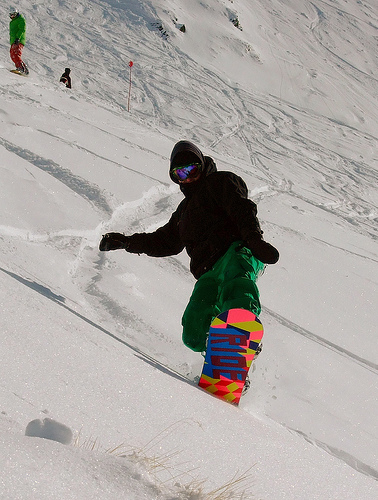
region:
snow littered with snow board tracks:
[161, 69, 281, 123]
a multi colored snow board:
[190, 313, 266, 395]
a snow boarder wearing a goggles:
[116, 149, 286, 407]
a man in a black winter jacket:
[108, 134, 302, 411]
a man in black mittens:
[89, 142, 282, 404]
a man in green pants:
[156, 137, 285, 395]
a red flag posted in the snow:
[114, 57, 141, 125]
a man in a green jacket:
[5, 3, 27, 79]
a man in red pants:
[5, 0, 40, 81]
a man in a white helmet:
[0, 5, 32, 55]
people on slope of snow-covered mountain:
[3, 3, 365, 487]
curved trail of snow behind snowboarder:
[72, 140, 285, 400]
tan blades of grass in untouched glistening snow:
[8, 404, 320, 495]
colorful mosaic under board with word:
[193, 304, 264, 407]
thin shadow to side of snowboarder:
[7, 133, 280, 407]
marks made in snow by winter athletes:
[6, 0, 374, 228]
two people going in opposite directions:
[3, 4, 76, 90]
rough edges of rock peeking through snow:
[142, 9, 252, 43]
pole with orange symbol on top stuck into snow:
[122, 57, 134, 115]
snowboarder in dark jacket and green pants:
[99, 131, 282, 351]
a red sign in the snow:
[118, 54, 138, 119]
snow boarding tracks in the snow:
[232, 103, 316, 167]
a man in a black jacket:
[107, 130, 280, 418]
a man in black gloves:
[109, 135, 277, 408]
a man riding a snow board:
[122, 131, 288, 417]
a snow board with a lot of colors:
[199, 308, 261, 412]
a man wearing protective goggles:
[109, 138, 292, 406]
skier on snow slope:
[94, 132, 283, 415]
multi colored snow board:
[194, 305, 263, 408]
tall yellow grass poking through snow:
[108, 403, 259, 496]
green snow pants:
[175, 240, 271, 360]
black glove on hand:
[96, 226, 133, 261]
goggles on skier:
[166, 160, 202, 184]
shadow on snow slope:
[1, 260, 195, 424]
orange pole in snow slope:
[122, 57, 139, 114]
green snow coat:
[6, 12, 30, 47]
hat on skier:
[167, 147, 201, 169]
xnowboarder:
[140, 118, 281, 404]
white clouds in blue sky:
[48, 14, 92, 32]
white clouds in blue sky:
[276, 14, 309, 31]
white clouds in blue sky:
[100, 12, 144, 46]